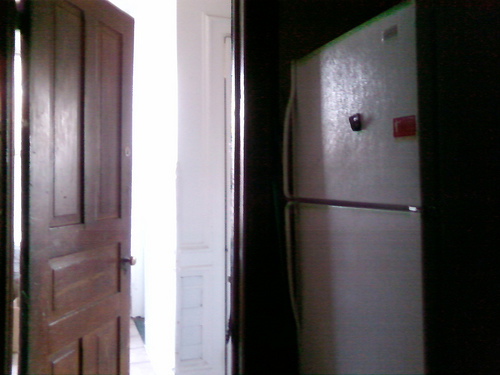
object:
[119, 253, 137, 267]
doorknob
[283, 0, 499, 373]
freezer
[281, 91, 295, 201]
handle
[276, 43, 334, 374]
shadow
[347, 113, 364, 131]
magnet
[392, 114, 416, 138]
magnet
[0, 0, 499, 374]
room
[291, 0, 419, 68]
line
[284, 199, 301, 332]
handle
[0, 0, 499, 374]
picture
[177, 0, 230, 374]
door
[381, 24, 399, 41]
decal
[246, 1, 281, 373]
wall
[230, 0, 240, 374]
edge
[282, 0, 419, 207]
door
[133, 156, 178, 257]
light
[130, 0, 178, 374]
doorway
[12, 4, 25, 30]
hinge